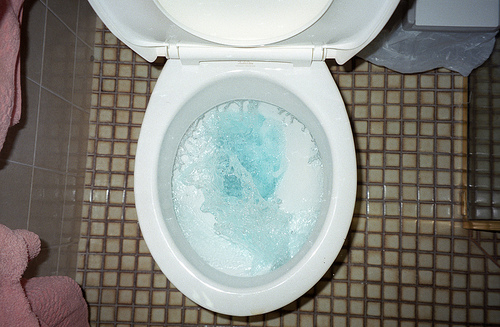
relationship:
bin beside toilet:
[405, 1, 500, 34] [88, 0, 407, 317]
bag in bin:
[358, 14, 499, 77] [405, 1, 500, 34]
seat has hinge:
[88, 0, 404, 67] [168, 46, 327, 65]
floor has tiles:
[73, 14, 499, 326] [75, 14, 500, 326]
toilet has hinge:
[88, 0, 407, 317] [168, 46, 327, 65]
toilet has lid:
[88, 0, 407, 317] [156, 0, 332, 46]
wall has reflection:
[1, 2, 98, 280] [33, 1, 95, 282]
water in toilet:
[173, 98, 329, 281] [88, 0, 407, 317]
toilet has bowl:
[88, 0, 407, 317] [133, 60, 358, 319]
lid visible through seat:
[156, 0, 332, 46] [154, 74, 351, 263]